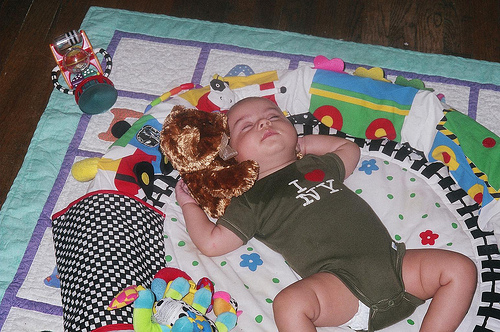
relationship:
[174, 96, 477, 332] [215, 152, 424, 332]
baby wearing onesie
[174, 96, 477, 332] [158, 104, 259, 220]
baby with bear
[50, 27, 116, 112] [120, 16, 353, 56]
toy on floor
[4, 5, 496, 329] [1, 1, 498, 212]
blanket laying on floor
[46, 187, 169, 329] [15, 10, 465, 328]
checkered blanket on floor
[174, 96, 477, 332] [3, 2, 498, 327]
baby on bed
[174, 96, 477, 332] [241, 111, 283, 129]
baby with eyes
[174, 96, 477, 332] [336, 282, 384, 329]
baby wearing diaper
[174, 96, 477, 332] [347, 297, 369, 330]
baby wearing diaper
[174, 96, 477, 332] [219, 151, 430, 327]
baby wearing onesie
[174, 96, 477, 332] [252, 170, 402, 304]
baby wearing onesie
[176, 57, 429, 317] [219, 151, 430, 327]
baby wearing onesie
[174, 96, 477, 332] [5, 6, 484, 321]
baby sleeping on ground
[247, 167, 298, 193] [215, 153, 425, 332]
spot on clothes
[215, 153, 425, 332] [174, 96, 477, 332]
clothes of baby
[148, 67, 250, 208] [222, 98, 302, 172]
bear near head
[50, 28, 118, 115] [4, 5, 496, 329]
toy on blanket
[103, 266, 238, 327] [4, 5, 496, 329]
toy on blanket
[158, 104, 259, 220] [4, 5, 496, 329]
bear on blanket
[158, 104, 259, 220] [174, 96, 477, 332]
bear next to baby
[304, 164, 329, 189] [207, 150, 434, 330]
heart on clothes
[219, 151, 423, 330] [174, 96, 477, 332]
clothes on baby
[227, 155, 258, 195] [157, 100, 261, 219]
paw of bear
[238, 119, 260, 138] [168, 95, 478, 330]
eye of infant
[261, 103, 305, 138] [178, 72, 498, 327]
eye of infant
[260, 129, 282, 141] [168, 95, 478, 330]
mouth of infant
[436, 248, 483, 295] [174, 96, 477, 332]
knee of baby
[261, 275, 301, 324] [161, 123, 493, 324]
knee of infant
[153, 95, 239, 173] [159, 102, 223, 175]
head of bear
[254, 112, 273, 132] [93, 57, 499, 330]
nose of infant